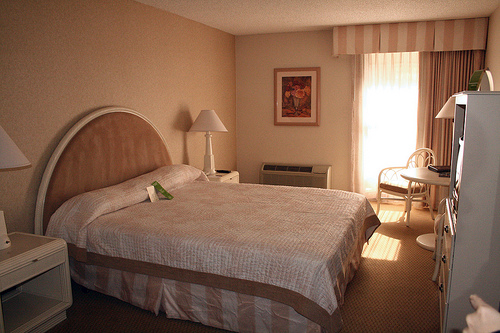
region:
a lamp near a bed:
[174, 71, 286, 179]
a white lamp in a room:
[193, 95, 264, 153]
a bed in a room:
[56, 145, 433, 330]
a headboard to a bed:
[11, 65, 247, 236]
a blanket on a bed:
[103, 139, 425, 299]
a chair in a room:
[351, 134, 478, 213]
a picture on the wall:
[234, 51, 405, 131]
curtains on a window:
[307, 42, 485, 170]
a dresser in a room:
[408, 52, 497, 299]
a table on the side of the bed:
[3, 206, 93, 318]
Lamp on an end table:
[187, 104, 242, 185]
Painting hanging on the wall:
[269, 63, 323, 131]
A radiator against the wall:
[256, 155, 336, 189]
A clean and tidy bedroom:
[1, 1, 498, 331]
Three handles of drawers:
[433, 219, 453, 299]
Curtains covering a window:
[349, 48, 482, 206]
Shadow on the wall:
[166, 102, 197, 165]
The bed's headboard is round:
[29, 101, 180, 236]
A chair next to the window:
[370, 143, 444, 229]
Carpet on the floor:
[45, 202, 443, 330]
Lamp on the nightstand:
[188, 103, 227, 179]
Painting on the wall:
[271, 65, 324, 127]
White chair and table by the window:
[373, 144, 455, 222]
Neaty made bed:
[34, 100, 381, 331]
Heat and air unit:
[256, 156, 334, 185]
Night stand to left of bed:
[0, 230, 75, 331]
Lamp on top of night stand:
[4, 121, 30, 247]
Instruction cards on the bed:
[143, 177, 171, 204]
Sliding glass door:
[358, 47, 489, 202]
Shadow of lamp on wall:
[172, 104, 196, 165]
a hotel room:
[2, 9, 492, 332]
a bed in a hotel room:
[46, 105, 371, 332]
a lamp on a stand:
[187, 108, 229, 176]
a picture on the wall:
[269, 60, 320, 132]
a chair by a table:
[378, 144, 437, 224]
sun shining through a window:
[352, 61, 426, 209]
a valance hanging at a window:
[320, 13, 495, 58]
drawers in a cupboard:
[431, 197, 451, 319]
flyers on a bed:
[143, 176, 178, 211]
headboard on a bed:
[33, 105, 179, 211]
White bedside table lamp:
[192, 106, 228, 176]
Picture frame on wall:
[265, 62, 327, 131]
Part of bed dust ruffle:
[96, 274, 169, 303]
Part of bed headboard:
[67, 122, 158, 151]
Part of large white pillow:
[68, 182, 152, 199]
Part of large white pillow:
[161, 172, 192, 184]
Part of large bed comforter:
[161, 211, 285, 261]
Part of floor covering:
[382, 263, 425, 305]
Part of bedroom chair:
[376, 145, 414, 190]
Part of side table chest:
[8, 255, 73, 311]